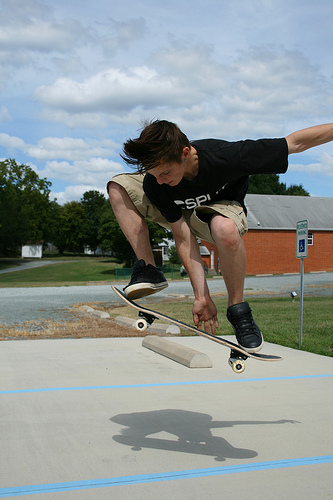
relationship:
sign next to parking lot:
[292, 218, 308, 257] [3, 330, 330, 498]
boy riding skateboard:
[124, 141, 240, 257] [115, 286, 281, 382]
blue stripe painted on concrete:
[47, 357, 217, 496] [98, 383, 189, 435]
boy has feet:
[106, 117, 332, 356] [224, 300, 263, 354]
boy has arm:
[106, 117, 332, 356] [165, 215, 214, 305]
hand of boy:
[191, 296, 219, 333] [106, 117, 332, 356]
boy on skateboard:
[106, 117, 332, 356] [108, 285, 284, 373]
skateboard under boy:
[108, 285, 284, 373] [106, 117, 332, 356]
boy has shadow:
[106, 117, 332, 356] [108, 407, 302, 462]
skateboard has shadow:
[108, 285, 284, 373] [108, 407, 302, 462]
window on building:
[306, 234, 313, 243] [193, 191, 331, 276]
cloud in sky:
[1, 16, 283, 123] [0, 0, 330, 177]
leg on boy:
[102, 179, 154, 267] [106, 117, 332, 356]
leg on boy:
[209, 206, 257, 311] [106, 117, 332, 356]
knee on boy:
[109, 176, 137, 212] [106, 117, 332, 356]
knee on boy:
[213, 215, 240, 244] [106, 117, 332, 356]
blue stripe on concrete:
[0, 371, 332, 395] [1, 331, 332, 498]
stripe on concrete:
[1, 450, 331, 498] [1, 331, 332, 498]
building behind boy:
[193, 191, 331, 276] [106, 117, 332, 356]